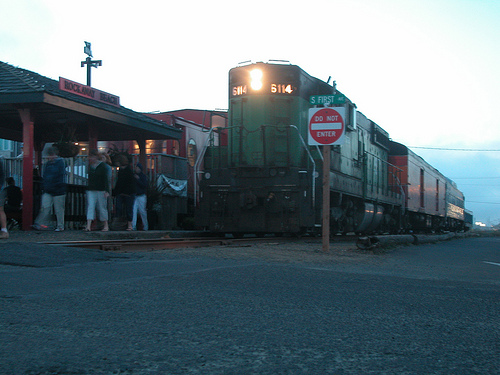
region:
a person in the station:
[1, 172, 21, 221]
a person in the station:
[0, 167, 7, 240]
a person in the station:
[28, 141, 64, 238]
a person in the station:
[76, 147, 114, 236]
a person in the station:
[119, 153, 166, 253]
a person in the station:
[115, 152, 144, 232]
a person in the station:
[101, 149, 118, 199]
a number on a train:
[231, 84, 239, 96]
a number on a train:
[268, 79, 275, 95]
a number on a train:
[283, 77, 294, 102]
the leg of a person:
[136, 195, 158, 230]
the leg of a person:
[124, 199, 140, 236]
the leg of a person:
[97, 193, 112, 235]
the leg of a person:
[80, 197, 97, 235]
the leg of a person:
[54, 193, 70, 234]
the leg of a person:
[28, 188, 56, 238]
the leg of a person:
[0, 200, 20, 242]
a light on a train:
[246, 65, 267, 100]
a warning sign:
[303, 101, 347, 154]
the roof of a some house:
[1, 59, 174, 141]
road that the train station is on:
[108, 279, 458, 346]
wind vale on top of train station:
[39, 35, 143, 118]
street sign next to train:
[301, 80, 362, 165]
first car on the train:
[200, 51, 319, 257]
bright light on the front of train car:
[227, 61, 279, 99]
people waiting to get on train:
[18, 140, 168, 235]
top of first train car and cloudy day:
[175, 0, 358, 68]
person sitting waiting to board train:
[0, 181, 35, 237]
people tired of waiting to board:
[0, 130, 166, 243]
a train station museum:
[26, 79, 482, 309]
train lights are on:
[230, 63, 287, 109]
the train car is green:
[237, 62, 395, 199]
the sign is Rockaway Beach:
[56, 73, 139, 111]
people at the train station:
[7, 116, 181, 226]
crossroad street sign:
[72, 31, 117, 88]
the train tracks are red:
[36, 230, 261, 267]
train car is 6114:
[223, 72, 318, 109]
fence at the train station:
[54, 147, 187, 221]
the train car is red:
[388, 142, 455, 219]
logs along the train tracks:
[346, 228, 494, 245]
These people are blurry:
[31, 135, 154, 235]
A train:
[215, 49, 488, 248]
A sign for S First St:
[306, 85, 349, 106]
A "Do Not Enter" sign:
[304, 105, 351, 150]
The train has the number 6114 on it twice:
[225, 57, 302, 104]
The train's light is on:
[226, 60, 282, 97]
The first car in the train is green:
[195, 52, 404, 244]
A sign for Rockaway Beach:
[51, 72, 128, 114]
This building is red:
[126, 105, 232, 178]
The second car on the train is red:
[386, 132, 453, 239]